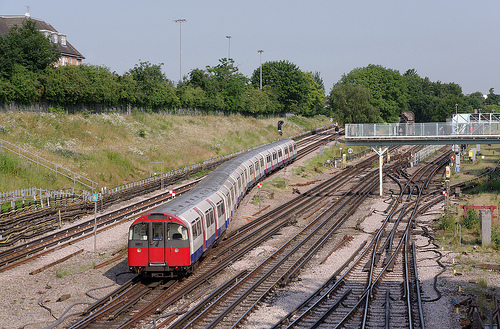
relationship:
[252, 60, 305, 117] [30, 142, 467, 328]
tree above tracks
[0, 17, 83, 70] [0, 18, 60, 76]
house behind tree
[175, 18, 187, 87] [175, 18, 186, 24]
post with light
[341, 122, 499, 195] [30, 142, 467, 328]
platform above tracks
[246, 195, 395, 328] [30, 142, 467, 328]
gravel between tracks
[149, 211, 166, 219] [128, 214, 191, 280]
sign on front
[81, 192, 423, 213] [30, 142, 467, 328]
row of train tracks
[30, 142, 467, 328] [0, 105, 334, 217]
tracks next to a hill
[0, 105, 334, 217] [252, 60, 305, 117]
hill next to tree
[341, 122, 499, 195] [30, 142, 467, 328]
platform over tracks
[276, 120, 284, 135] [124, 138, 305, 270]
signal behind train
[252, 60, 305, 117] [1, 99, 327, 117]
tree along fence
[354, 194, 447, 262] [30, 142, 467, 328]
intersection on tracks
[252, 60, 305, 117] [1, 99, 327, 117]
tree lining fence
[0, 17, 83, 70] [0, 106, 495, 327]
house overlooking station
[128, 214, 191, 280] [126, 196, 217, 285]
front of car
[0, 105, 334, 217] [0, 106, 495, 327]
hill next to station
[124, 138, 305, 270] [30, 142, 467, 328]
train on tracks